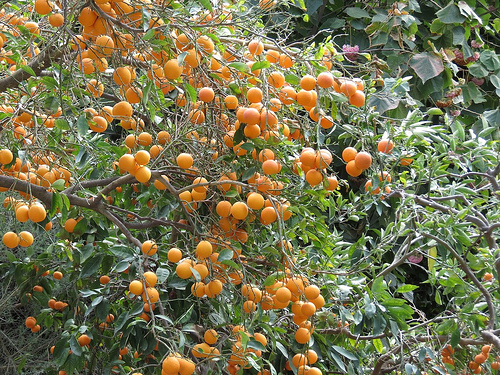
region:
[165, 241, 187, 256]
tiny yellow fruit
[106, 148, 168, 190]
cluster of yellow fruits on vine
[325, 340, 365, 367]
green leaves on the vine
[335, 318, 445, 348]
small branch on the vine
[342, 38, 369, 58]
tiny purple leaf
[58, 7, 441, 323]
tree with yellow fruit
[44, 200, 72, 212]
tiny brown spot on leaf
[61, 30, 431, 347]
some orange colored fruit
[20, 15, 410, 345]
the fruit is growing on trees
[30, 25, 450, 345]
the trees have green leaves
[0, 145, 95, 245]
one of the trees branches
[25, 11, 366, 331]
the fruit is orange in color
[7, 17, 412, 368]
the fruit growing on the trees is oranges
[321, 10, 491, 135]
the leaves are green in color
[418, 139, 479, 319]
some of the trees branches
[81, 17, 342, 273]
oranges grow on the trees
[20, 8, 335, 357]
a lot of oranges grow in the trees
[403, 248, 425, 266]
Small purple pedal on tree.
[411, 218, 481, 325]
Brown stick with leaves.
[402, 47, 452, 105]
Big green and pink leaf.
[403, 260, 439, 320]
Dark hole in the tree.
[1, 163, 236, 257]
Small branch with bunch of fruit.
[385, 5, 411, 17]
Small brown leaves in the bush.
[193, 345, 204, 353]
Small green leaf on side of date.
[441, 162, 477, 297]
Bunch of small trees to the right.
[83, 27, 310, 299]
several fruits growing on a tree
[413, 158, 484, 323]
green leaves on the tree branches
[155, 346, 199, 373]
a bunch of oraqnge fruits on a tree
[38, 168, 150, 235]
grey branch of the tree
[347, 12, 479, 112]
several purple blossoms on the tree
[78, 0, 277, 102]
several leafless branches of the tree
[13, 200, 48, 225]
orange fruits hanging from the tree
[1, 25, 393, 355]
many bunches of peaches hanging from a tree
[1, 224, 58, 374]
branch of a pine tree behind the fruit tree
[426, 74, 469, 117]
dead brown blossoms of a plant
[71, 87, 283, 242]
orange things on the tree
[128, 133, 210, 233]
branches on the tree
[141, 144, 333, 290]
many different round things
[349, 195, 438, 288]
leaves on the tree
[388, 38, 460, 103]
leaf on the tree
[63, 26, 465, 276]
green and orange stuff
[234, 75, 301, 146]
a bunch of different oranges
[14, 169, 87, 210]
long branch in the photo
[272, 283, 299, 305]
round object in the photo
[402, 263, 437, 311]
leaves in the background